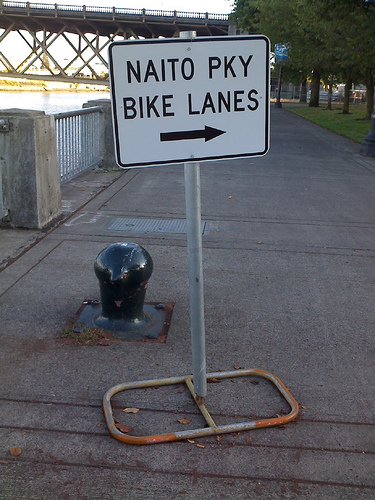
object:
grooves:
[1, 392, 374, 489]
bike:
[121, 90, 176, 117]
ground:
[345, 98, 357, 112]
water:
[30, 89, 75, 112]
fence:
[53, 99, 103, 178]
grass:
[314, 109, 363, 128]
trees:
[282, 0, 374, 121]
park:
[276, 1, 372, 148]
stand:
[185, 163, 208, 312]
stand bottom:
[96, 365, 302, 445]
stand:
[101, 364, 299, 451]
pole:
[185, 163, 208, 397]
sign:
[107, 32, 270, 162]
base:
[99, 361, 303, 446]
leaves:
[106, 399, 202, 433]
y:
[239, 51, 256, 75]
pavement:
[198, 199, 363, 300]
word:
[184, 91, 259, 116]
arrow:
[158, 118, 230, 146]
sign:
[272, 40, 289, 63]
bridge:
[10, 8, 319, 87]